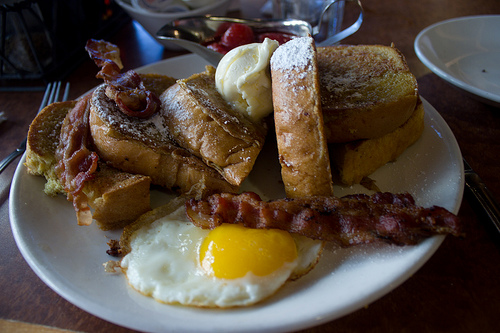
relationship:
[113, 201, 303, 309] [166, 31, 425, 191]
eggs near bread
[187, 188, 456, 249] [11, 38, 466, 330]
bacon on plate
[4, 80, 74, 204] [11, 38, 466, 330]
fork next to plate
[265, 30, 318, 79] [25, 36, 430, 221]
sugar on french toast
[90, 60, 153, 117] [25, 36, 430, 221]
bacon on french toast